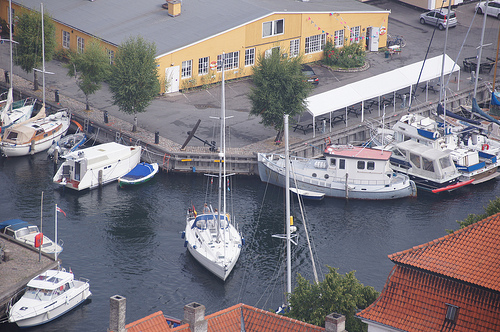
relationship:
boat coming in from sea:
[256, 148, 417, 202] [1, 149, 499, 330]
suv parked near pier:
[414, 4, 461, 32] [0, 65, 497, 182]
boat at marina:
[7, 258, 95, 328] [0, 82, 498, 330]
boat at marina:
[118, 152, 163, 192] [1, 0, 499, 210]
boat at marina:
[185, 189, 245, 281] [1, 0, 499, 210]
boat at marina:
[256, 144, 417, 201] [1, 0, 499, 210]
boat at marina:
[0, 191, 65, 259] [0, 82, 498, 330]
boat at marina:
[36, 130, 87, 158] [0, 82, 498, 330]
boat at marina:
[368, 0, 498, 186] [1, 0, 498, 330]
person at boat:
[183, 203, 203, 227] [176, 194, 257, 281]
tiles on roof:
[398, 289, 423, 309] [348, 192, 498, 328]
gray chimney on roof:
[180, 298, 207, 330] [163, 300, 332, 330]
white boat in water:
[60, 135, 145, 193] [98, 221, 179, 276]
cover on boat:
[122, 161, 153, 176] [113, 160, 160, 184]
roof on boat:
[331, 144, 390, 164] [293, 173, 393, 203]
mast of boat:
[216, 60, 231, 240] [178, 61, 245, 282]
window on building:
[176, 57, 193, 79] [0, 0, 390, 94]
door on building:
[163, 66, 183, 94] [0, 0, 390, 94]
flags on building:
[305, 11, 386, 42] [0, 0, 390, 94]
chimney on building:
[167, 0, 182, 16] [0, 0, 390, 94]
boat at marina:
[351, 138, 477, 193] [58, 138, 460, 320]